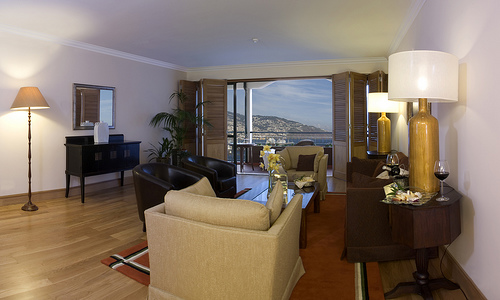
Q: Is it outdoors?
A: Yes, it is outdoors.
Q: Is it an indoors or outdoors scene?
A: It is outdoors.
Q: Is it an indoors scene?
A: No, it is outdoors.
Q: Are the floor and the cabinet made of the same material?
A: Yes, both the floor and the cabinet are made of wood.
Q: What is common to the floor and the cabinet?
A: The material, both the floor and the cabinet are wooden.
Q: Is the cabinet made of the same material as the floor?
A: Yes, both the cabinet and the floor are made of wood.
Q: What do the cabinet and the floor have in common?
A: The material, both the cabinet and the floor are wooden.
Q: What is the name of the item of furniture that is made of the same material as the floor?
A: The piece of furniture is a cabinet.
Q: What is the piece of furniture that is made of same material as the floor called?
A: The piece of furniture is a cabinet.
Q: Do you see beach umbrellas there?
A: No, there are no beach umbrellas.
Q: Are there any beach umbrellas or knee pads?
A: No, there are no beach umbrellas or knee pads.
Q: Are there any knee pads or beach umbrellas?
A: No, there are no beach umbrellas or knee pads.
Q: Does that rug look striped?
A: Yes, the rug is striped.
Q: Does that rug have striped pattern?
A: Yes, the rug is striped.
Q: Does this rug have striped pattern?
A: Yes, the rug is striped.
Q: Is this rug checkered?
A: No, the rug is striped.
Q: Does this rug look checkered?
A: No, the rug is striped.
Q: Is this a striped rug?
A: Yes, this is a striped rug.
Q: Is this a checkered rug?
A: No, this is a striped rug.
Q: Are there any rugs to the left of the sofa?
A: Yes, there is a rug to the left of the sofa.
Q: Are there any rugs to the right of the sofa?
A: No, the rug is to the left of the sofa.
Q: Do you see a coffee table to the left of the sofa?
A: No, there is a rug to the left of the sofa.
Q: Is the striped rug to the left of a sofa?
A: Yes, the rug is to the left of a sofa.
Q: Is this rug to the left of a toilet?
A: No, the rug is to the left of a sofa.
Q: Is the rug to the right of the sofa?
A: No, the rug is to the left of the sofa.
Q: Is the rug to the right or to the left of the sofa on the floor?
A: The rug is to the left of the sofa.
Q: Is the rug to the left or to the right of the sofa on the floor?
A: The rug is to the left of the sofa.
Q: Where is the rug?
A: The rug is on the floor.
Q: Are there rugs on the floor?
A: Yes, there is a rug on the floor.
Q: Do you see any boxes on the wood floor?
A: No, there is a rug on the floor.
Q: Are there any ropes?
A: No, there are no ropes.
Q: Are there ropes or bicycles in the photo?
A: No, there are no ropes or bicycles.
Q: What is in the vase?
A: The flower is in the vase.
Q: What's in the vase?
A: The flower is in the vase.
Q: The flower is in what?
A: The flower is in the vase.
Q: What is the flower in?
A: The flower is in the vase.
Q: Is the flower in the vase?
A: Yes, the flower is in the vase.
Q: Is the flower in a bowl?
A: No, the flower is in the vase.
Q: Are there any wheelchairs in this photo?
A: No, there are no wheelchairs.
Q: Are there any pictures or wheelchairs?
A: No, there are no wheelchairs or pictures.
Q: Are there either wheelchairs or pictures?
A: No, there are no wheelchairs or pictures.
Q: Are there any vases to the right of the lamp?
A: No, the vase is to the left of the lamp.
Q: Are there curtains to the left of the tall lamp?
A: No, there is a vase to the left of the lamp.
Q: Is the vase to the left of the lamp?
A: Yes, the vase is to the left of the lamp.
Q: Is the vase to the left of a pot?
A: No, the vase is to the left of the lamp.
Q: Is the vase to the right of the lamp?
A: No, the vase is to the left of the lamp.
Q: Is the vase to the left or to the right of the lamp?
A: The vase is to the left of the lamp.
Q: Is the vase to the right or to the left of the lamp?
A: The vase is to the left of the lamp.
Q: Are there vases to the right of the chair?
A: Yes, there is a vase to the right of the chair.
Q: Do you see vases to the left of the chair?
A: No, the vase is to the right of the chair.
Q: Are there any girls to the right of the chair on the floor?
A: No, there is a vase to the right of the chair.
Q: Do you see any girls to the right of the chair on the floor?
A: No, there is a vase to the right of the chair.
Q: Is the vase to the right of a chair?
A: Yes, the vase is to the right of a chair.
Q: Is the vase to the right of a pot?
A: No, the vase is to the right of a chair.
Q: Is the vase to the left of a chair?
A: No, the vase is to the right of a chair.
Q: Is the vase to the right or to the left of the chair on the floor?
A: The vase is to the right of the chair.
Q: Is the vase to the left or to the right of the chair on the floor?
A: The vase is to the right of the chair.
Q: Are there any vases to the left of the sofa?
A: Yes, there is a vase to the left of the sofa.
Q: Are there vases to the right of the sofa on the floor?
A: No, the vase is to the left of the sofa.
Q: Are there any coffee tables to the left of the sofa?
A: No, there is a vase to the left of the sofa.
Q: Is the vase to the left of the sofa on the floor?
A: Yes, the vase is to the left of the sofa.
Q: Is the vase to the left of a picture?
A: No, the vase is to the left of the sofa.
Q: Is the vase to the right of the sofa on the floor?
A: No, the vase is to the left of the sofa.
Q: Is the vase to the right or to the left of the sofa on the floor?
A: The vase is to the left of the sofa.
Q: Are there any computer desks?
A: No, there are no computer desks.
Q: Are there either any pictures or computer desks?
A: No, there are no computer desks or pictures.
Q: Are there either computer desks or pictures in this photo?
A: No, there are no computer desks or pictures.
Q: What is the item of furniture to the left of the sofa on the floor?
A: The piece of furniture is an armchair.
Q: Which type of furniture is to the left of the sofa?
A: The piece of furniture is an armchair.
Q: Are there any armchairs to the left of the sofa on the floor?
A: Yes, there is an armchair to the left of the sofa.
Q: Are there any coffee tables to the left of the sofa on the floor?
A: No, there is an armchair to the left of the sofa.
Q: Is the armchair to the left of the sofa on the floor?
A: Yes, the armchair is to the left of the sofa.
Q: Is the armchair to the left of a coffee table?
A: No, the armchair is to the left of the sofa.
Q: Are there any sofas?
A: Yes, there is a sofa.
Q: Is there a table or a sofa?
A: Yes, there is a sofa.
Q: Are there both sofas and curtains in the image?
A: No, there is a sofa but no curtains.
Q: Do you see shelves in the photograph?
A: No, there are no shelves.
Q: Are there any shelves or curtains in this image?
A: No, there are no shelves or curtains.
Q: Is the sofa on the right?
A: Yes, the sofa is on the right of the image.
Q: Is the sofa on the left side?
A: No, the sofa is on the right of the image.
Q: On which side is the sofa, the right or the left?
A: The sofa is on the right of the image.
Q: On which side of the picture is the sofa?
A: The sofa is on the right of the image.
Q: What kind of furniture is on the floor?
A: The piece of furniture is a sofa.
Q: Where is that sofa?
A: The sofa is on the floor.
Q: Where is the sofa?
A: The sofa is on the floor.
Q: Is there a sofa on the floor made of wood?
A: Yes, there is a sofa on the floor.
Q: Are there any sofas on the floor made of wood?
A: Yes, there is a sofa on the floor.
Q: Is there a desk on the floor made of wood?
A: No, there is a sofa on the floor.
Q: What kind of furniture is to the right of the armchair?
A: The piece of furniture is a sofa.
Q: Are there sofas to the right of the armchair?
A: Yes, there is a sofa to the right of the armchair.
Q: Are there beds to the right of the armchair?
A: No, there is a sofa to the right of the armchair.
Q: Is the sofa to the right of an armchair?
A: Yes, the sofa is to the right of an armchair.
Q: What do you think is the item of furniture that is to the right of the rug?
A: The piece of furniture is a sofa.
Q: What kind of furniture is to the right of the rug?
A: The piece of furniture is a sofa.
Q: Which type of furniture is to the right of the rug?
A: The piece of furniture is a sofa.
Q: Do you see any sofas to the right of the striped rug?
A: Yes, there is a sofa to the right of the rug.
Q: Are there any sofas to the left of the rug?
A: No, the sofa is to the right of the rug.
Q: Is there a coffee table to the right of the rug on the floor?
A: No, there is a sofa to the right of the rug.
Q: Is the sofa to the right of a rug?
A: Yes, the sofa is to the right of a rug.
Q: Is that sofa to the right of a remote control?
A: No, the sofa is to the right of a rug.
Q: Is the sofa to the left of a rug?
A: No, the sofa is to the right of a rug.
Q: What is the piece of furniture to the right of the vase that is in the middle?
A: The piece of furniture is a sofa.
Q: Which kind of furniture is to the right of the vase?
A: The piece of furniture is a sofa.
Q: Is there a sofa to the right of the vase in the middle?
A: Yes, there is a sofa to the right of the vase.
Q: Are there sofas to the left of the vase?
A: No, the sofa is to the right of the vase.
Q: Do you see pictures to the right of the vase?
A: No, there is a sofa to the right of the vase.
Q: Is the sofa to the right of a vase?
A: Yes, the sofa is to the right of a vase.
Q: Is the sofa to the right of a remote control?
A: No, the sofa is to the right of a vase.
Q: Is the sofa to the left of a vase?
A: No, the sofa is to the right of a vase.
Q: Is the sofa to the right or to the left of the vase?
A: The sofa is to the right of the vase.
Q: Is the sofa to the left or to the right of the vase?
A: The sofa is to the right of the vase.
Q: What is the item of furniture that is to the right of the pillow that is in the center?
A: The piece of furniture is a sofa.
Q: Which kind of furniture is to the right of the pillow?
A: The piece of furniture is a sofa.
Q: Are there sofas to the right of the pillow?
A: Yes, there is a sofa to the right of the pillow.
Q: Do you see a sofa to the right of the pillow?
A: Yes, there is a sofa to the right of the pillow.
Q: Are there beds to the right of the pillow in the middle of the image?
A: No, there is a sofa to the right of the pillow.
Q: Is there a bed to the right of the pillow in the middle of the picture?
A: No, there is a sofa to the right of the pillow.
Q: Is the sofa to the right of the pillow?
A: Yes, the sofa is to the right of the pillow.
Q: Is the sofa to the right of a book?
A: No, the sofa is to the right of the pillow.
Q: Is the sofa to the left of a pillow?
A: No, the sofa is to the right of a pillow.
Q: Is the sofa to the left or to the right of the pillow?
A: The sofa is to the right of the pillow.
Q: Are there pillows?
A: Yes, there is a pillow.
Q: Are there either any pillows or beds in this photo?
A: Yes, there is a pillow.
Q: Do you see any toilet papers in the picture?
A: No, there are no toilet papers.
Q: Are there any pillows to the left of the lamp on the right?
A: Yes, there is a pillow to the left of the lamp.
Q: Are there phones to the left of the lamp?
A: No, there is a pillow to the left of the lamp.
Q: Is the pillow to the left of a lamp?
A: Yes, the pillow is to the left of a lamp.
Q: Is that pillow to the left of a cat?
A: No, the pillow is to the left of a lamp.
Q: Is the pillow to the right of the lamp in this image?
A: No, the pillow is to the left of the lamp.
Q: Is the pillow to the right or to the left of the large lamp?
A: The pillow is to the left of the lamp.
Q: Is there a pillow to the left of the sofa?
A: Yes, there is a pillow to the left of the sofa.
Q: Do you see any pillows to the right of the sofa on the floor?
A: No, the pillow is to the left of the sofa.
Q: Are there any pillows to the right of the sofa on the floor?
A: No, the pillow is to the left of the sofa.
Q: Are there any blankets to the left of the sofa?
A: No, there is a pillow to the left of the sofa.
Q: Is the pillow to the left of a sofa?
A: Yes, the pillow is to the left of a sofa.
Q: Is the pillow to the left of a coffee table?
A: No, the pillow is to the left of a sofa.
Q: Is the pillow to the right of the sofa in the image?
A: No, the pillow is to the left of the sofa.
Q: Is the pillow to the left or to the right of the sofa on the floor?
A: The pillow is to the left of the sofa.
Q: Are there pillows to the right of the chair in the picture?
A: Yes, there is a pillow to the right of the chair.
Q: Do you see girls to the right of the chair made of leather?
A: No, there is a pillow to the right of the chair.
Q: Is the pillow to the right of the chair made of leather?
A: Yes, the pillow is to the right of the chair.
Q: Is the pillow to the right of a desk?
A: No, the pillow is to the right of the chair.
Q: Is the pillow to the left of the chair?
A: No, the pillow is to the right of the chair.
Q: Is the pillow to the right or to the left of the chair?
A: The pillow is to the right of the chair.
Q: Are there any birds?
A: No, there are no birds.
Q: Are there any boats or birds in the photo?
A: No, there are no birds or boats.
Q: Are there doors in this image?
A: Yes, there is a door.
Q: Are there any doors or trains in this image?
A: Yes, there is a door.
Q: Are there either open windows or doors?
A: Yes, there is an open door.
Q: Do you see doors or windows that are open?
A: Yes, the door is open.